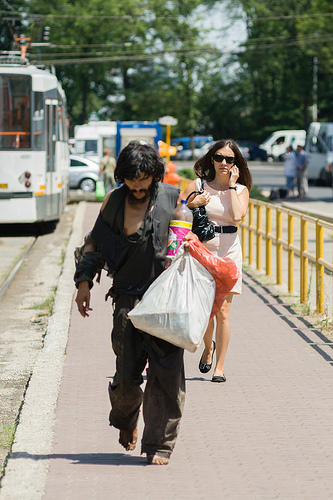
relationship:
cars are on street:
[173, 118, 308, 158] [162, 144, 299, 184]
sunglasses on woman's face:
[210, 151, 237, 164] [210, 151, 234, 174]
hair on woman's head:
[192, 134, 252, 191] [206, 138, 236, 179]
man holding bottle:
[73, 142, 200, 459] [161, 196, 194, 264]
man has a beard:
[73, 142, 200, 459] [125, 185, 149, 203]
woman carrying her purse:
[182, 135, 254, 387] [185, 188, 214, 242]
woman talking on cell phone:
[182, 135, 254, 387] [227, 163, 237, 179]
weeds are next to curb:
[25, 279, 58, 318] [0, 197, 90, 499]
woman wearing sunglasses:
[182, 135, 254, 387] [210, 151, 237, 164]